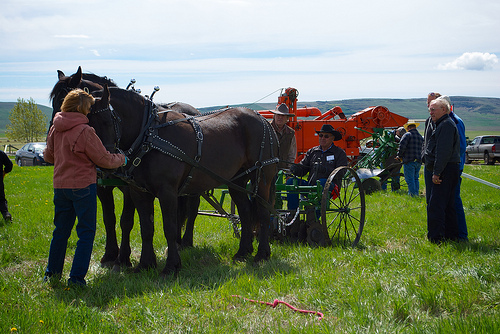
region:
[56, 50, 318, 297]
Two horse are standing.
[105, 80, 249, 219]
Horse are brown color.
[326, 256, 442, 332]
Grass are green color.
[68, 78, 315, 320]
Horse is standing in graee.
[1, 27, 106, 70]
Sky is blue color.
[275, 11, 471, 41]
Clouds are white color.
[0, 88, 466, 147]
Foot hill is seen behind the horse.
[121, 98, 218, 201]
Belt is black color.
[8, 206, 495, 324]
Shadow falls on grass.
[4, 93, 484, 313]
People are standing in grass.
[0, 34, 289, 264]
TWO BROWN HORSES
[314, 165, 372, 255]
A WAGON WHEEL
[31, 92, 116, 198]
A WOMAN IN A RED JACKET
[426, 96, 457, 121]
A MAN WEARING GLASSES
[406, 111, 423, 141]
A MAN WEARING A COWBOY HAT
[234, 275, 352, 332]
A RED ROPE ON THE GROUND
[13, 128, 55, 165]
A CAR PARKED IN A FIELD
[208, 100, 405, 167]
RED FARM EQUIPMENT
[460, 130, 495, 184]
A TRUCK PARKED IN A FIELD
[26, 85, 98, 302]
A WOMAN WEARING BLUE JEANS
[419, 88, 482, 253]
Group of people looking at horse and plow.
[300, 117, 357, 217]
Man sitting on plow.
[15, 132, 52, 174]
Car parked in field.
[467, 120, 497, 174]
Truck parked in field.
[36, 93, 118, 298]
Woman helping harness horses to plow.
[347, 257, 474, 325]
Lush green grass.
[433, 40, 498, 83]
Cloud hanging in the sky.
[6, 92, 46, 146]
Three threes with mountain in the background.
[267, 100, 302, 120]
Tan cowboy hat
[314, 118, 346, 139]
Black cowboy hat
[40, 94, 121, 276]
a woman standing next to some horses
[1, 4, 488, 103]
the blue sky above everything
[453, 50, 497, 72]
a single cloud in the sky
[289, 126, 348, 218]
a man sitting behind the horses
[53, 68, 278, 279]
two big brown horses in the field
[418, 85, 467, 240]
three men looking at the horses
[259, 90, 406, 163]
a big red farming device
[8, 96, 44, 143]
some trees behind the cars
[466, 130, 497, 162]
a truck parked in the field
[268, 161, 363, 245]
a farming device connected to the horses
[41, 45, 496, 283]
brown horse with wheels attached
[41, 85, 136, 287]
woman in pink shirt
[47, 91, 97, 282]
woman in blue jeans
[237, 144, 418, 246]
wheels on green contraption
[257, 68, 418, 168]
red tractor in background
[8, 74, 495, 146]
rolling hills in background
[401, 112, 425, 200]
person in plaid shirt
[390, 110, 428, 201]
person in blue jeans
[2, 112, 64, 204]
vehicle on left of photo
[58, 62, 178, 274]
woman touching brown horse